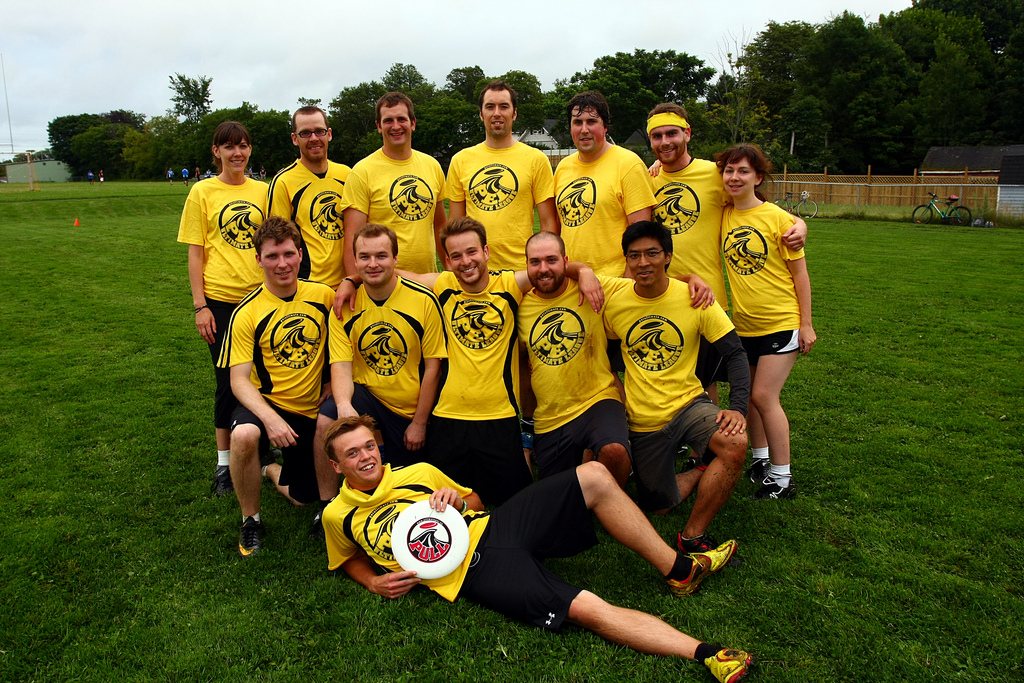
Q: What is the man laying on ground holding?
A: Frisbee.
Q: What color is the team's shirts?
A: Yellow.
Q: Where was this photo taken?
A: Park.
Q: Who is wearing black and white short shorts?
A: Girl on right on picture.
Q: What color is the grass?
A: Green.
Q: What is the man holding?
A: A frisbee.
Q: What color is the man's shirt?
A: Yellow.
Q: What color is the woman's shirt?
A: Yellow.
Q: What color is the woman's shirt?
A: Yellow.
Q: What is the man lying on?
A: The ground.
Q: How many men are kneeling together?
A: Five.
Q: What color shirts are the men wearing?
A: Yellow.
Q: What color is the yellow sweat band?
A: Yellow.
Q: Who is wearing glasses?
A: A man.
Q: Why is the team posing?
A: They are in a photograph.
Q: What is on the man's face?
A: A beard and mustache.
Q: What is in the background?
A: Trees.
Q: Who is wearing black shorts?
A: A guy.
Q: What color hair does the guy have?
A: Black.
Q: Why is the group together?
A: They are posing for pictures.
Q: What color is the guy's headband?
A: Yellow.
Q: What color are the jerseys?
A: Yellow.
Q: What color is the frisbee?
A: White.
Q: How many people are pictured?
A: Thirteen.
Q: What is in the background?
A: Trees.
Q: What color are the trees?
A: Green.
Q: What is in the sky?
A: Clouds.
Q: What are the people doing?
A: Posing for a picture.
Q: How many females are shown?
A: Two.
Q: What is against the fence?
A: A bicycle.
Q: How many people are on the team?
A: 13.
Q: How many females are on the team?
A: 2.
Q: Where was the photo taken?
A: Grass field.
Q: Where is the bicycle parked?
A: Against chain link fence.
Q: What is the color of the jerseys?
A: Yellow and black.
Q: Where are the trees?
A: Background.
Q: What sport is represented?
A: Frisbee.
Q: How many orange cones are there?
A: 1.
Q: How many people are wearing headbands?
A: 1.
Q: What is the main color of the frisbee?
A: White.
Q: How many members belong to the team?
A: Thirteen.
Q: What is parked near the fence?
A: A bike.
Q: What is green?
A: The grass.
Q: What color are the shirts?
A: Yellow.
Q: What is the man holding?
A: Frisbee.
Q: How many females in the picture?
A: Two.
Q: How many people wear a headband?
A: One.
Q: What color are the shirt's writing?
A: Black.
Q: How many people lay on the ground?
A: One.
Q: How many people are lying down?
A: One.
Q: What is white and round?
A: Frisbee.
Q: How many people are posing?
A: Thirteen.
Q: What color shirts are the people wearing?
A: Yellow.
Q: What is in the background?
A: Trees.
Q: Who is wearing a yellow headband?
A: One man.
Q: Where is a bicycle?
A: In the distance.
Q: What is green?
A: Grass.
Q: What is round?
A: Frisbee.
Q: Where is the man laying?
A: On the grass.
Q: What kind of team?
A: Frisbee.